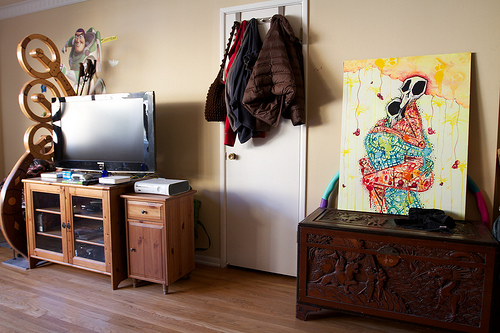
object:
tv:
[51, 90, 156, 173]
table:
[21, 175, 132, 291]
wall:
[153, 21, 165, 33]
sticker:
[61, 26, 117, 95]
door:
[224, 4, 301, 277]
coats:
[242, 14, 306, 128]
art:
[360, 75, 436, 214]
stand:
[307, 242, 381, 287]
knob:
[228, 153, 236, 160]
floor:
[0, 284, 299, 333]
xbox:
[134, 178, 190, 196]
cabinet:
[119, 189, 197, 294]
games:
[78, 226, 100, 240]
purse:
[204, 20, 240, 121]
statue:
[29, 48, 44, 59]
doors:
[26, 183, 112, 274]